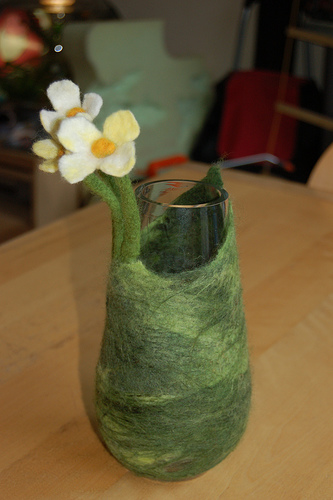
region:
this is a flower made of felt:
[48, 158, 258, 310]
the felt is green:
[95, 227, 206, 392]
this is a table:
[74, 469, 99, 498]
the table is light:
[45, 437, 78, 480]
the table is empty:
[63, 270, 78, 303]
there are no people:
[29, 348, 49, 384]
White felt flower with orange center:
[59, 113, 139, 178]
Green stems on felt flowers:
[86, 172, 142, 259]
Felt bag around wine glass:
[97, 258, 249, 475]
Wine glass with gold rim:
[137, 178, 226, 269]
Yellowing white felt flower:
[33, 140, 62, 171]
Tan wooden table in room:
[3, 162, 329, 498]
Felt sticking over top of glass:
[205, 161, 225, 184]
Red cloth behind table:
[224, 68, 294, 167]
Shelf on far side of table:
[274, 3, 332, 135]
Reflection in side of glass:
[147, 182, 188, 198]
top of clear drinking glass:
[135, 179, 241, 288]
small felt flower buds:
[33, 78, 155, 190]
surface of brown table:
[252, 226, 331, 334]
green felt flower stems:
[82, 178, 143, 263]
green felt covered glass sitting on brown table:
[28, 69, 288, 481]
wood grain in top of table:
[36, 403, 90, 468]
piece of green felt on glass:
[203, 154, 232, 175]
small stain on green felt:
[156, 456, 190, 478]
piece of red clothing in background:
[209, 60, 311, 176]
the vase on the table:
[31, 86, 261, 481]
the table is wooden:
[11, 160, 328, 481]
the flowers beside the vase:
[54, 113, 139, 204]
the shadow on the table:
[55, 226, 100, 383]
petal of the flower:
[43, 153, 88, 187]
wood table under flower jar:
[7, 153, 331, 394]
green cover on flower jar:
[84, 222, 293, 470]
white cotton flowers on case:
[53, 115, 141, 173]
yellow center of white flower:
[89, 132, 110, 155]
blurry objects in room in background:
[16, 17, 294, 175]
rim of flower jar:
[132, 170, 234, 209]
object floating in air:
[48, 40, 67, 50]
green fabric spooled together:
[127, 322, 216, 387]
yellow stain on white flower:
[103, 108, 142, 147]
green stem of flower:
[101, 186, 159, 256]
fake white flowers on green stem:
[35, 80, 141, 184]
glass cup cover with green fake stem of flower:
[135, 176, 231, 277]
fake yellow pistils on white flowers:
[61, 107, 114, 162]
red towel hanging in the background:
[215, 66, 303, 173]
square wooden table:
[0, 162, 326, 498]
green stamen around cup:
[89, 167, 254, 485]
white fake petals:
[33, 76, 142, 184]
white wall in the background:
[32, 13, 219, 228]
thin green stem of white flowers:
[81, 168, 140, 265]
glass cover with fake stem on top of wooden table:
[96, 173, 253, 483]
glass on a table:
[130, 173, 230, 279]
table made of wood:
[2, 148, 331, 499]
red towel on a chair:
[213, 65, 298, 166]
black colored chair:
[182, 65, 327, 185]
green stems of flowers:
[83, 170, 147, 268]